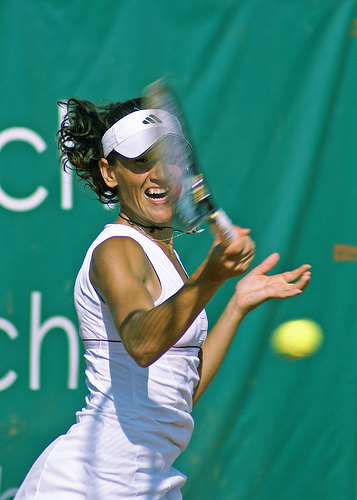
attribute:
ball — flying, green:
[263, 307, 331, 380]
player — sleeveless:
[4, 102, 230, 499]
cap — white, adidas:
[78, 102, 197, 175]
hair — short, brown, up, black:
[45, 90, 185, 204]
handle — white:
[196, 202, 254, 255]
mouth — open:
[130, 180, 187, 209]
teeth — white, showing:
[137, 185, 176, 203]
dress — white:
[13, 221, 206, 496]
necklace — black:
[112, 212, 217, 246]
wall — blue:
[190, 30, 334, 137]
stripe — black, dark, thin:
[78, 326, 218, 362]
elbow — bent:
[116, 321, 173, 369]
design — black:
[88, 108, 191, 158]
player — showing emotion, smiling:
[86, 119, 207, 227]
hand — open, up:
[229, 241, 319, 305]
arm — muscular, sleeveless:
[94, 240, 169, 354]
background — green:
[182, 3, 324, 89]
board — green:
[1, 2, 345, 498]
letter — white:
[1, 315, 17, 393]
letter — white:
[29, 288, 78, 389]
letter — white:
[1, 126, 47, 213]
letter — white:
[57, 98, 115, 210]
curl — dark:
[67, 113, 93, 138]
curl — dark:
[97, 190, 119, 199]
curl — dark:
[62, 96, 86, 112]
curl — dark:
[58, 140, 75, 148]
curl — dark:
[59, 114, 75, 125]